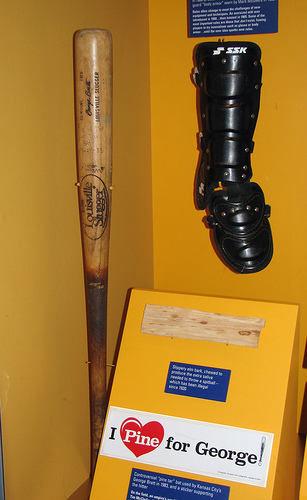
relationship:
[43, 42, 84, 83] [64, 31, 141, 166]
piece of pine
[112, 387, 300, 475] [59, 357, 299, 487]
sticker for bumper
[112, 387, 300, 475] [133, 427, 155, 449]
sticker has n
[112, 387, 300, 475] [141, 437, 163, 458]
sticker has e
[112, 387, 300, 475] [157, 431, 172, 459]
sticker has f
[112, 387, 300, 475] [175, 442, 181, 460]
sticker has o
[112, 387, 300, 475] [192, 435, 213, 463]
sticker has g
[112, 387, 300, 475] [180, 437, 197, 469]
sticker for r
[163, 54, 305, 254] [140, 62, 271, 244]
padding on wall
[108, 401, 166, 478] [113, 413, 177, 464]
heart says pine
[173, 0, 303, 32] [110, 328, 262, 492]
sign on display